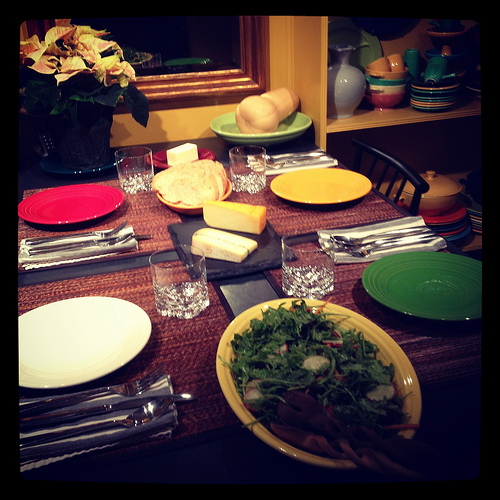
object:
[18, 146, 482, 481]
table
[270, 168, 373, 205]
plate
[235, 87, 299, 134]
vegetable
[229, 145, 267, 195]
glass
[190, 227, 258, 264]
cheese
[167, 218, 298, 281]
cutting board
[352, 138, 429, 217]
chair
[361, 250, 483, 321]
plate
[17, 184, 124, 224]
plate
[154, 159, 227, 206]
bread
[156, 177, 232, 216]
bowl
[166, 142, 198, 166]
stick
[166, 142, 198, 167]
butter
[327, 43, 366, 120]
vase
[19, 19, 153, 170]
plant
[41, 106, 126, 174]
pot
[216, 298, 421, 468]
bowl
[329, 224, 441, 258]
spoon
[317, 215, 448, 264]
napkin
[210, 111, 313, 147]
bowl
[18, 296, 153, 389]
plate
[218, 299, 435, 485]
salad